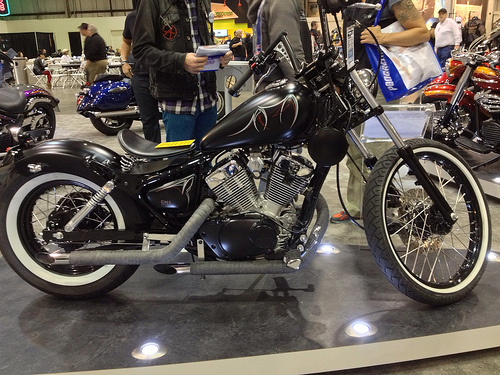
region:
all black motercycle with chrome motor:
[0, 1, 491, 321]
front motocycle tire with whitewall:
[362, 134, 494, 304]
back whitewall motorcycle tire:
[1, 172, 142, 300]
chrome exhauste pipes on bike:
[35, 199, 305, 276]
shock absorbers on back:
[59, 174, 116, 233]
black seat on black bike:
[112, 126, 197, 155]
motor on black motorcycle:
[200, 147, 305, 258]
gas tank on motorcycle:
[196, 77, 317, 149]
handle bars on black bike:
[222, 3, 382, 93]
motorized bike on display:
[11, 45, 496, 319]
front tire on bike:
[351, 140, 497, 307]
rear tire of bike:
[3, 158, 159, 289]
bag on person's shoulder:
[356, 21, 451, 95]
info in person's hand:
[190, 40, 234, 74]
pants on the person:
[166, 95, 218, 154]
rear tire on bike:
[83, 87, 138, 132]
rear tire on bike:
[21, 100, 68, 142]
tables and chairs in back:
[32, 47, 117, 77]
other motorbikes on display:
[439, 42, 499, 149]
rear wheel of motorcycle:
[0, 161, 141, 298]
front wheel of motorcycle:
[362, 137, 492, 306]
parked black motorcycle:
[5, 14, 491, 306]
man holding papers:
[132, 4, 232, 140]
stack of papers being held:
[198, 44, 228, 70]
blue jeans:
[160, 110, 224, 146]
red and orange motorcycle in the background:
[421, 32, 498, 150]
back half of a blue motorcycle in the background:
[77, 75, 140, 135]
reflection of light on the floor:
[132, 340, 166, 362]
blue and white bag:
[364, 1, 444, 103]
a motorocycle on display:
[22, 46, 489, 344]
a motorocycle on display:
[16, 59, 498, 345]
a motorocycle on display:
[2, 38, 479, 332]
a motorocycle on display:
[8, 58, 443, 328]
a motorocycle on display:
[27, 57, 499, 351]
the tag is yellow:
[139, 128, 207, 165]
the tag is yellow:
[150, 116, 212, 154]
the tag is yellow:
[140, 130, 205, 161]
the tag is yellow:
[144, 119, 204, 154]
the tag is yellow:
[144, 113, 204, 154]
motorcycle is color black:
[10, 7, 489, 315]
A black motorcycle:
[30, 50, 378, 335]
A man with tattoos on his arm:
[314, 4, 434, 116]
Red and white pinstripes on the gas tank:
[233, 83, 309, 139]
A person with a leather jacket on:
[116, 5, 217, 93]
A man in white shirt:
[416, 18, 458, 72]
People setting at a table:
[19, 29, 113, 93]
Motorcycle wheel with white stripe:
[0, 163, 119, 308]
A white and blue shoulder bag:
[311, 13, 445, 145]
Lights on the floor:
[128, 295, 380, 364]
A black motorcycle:
[72, 43, 330, 218]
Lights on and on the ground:
[141, 315, 391, 362]